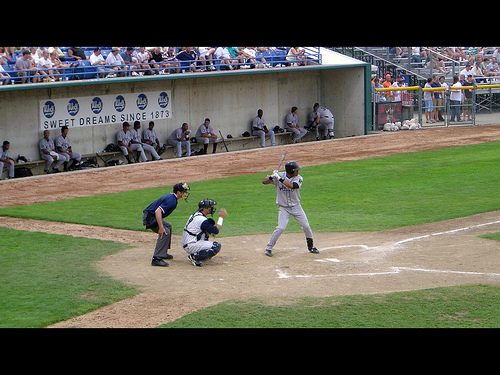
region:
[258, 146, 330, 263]
batter standing in the batter's box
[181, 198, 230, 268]
catcher crouched in the dirt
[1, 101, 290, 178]
baseball players sitting on the bench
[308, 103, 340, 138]
baseball player standing up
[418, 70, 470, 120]
spectators standing behind the chain link fence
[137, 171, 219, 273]
umpire hunched over behind the catcher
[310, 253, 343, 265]
homeplate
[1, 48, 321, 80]
spectators sitting in the stands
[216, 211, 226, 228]
thick white band on the arm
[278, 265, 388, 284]
white lines painted in the dirt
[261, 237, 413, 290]
Batter's box at a baseball field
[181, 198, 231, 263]
Catcher preparing to catch a pitch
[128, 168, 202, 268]
Umpire preparing to call a pitch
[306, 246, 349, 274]
Home plate in a baseball diamond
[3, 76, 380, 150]
Dugout area of baseball field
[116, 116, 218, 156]
Baseball players waiting to bat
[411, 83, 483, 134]
Steel gates for access to baseball field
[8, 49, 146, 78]
Spectators at a baseball game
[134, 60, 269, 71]
Safety railing for spectator area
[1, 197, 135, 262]
Path in grass leading to batter's box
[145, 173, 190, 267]
umpire behind catcher at home plate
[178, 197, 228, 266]
catcher awaiting ball to be thrown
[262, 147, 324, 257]
batter waiting for pitch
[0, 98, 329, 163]
players waiting in the dugout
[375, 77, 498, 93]
yellow guards on top of fence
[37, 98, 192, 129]
blue and white banner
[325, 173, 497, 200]
green grass on field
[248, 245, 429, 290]
home plate with scuff marks from sliders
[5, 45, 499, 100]
fans in the background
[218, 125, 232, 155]
bat leaning on bench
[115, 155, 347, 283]
baseball players on a field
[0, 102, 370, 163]
baseball players sitting on a long bench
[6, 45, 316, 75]
spectators watching baseball in the bleachers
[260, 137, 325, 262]
man holding a baseball bat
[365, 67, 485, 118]
people watching baseball behind a fence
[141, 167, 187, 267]
umpire wearing a blue shirt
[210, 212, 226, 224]
catcher wearing a white wristband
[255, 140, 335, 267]
baseball player ready to hit a ball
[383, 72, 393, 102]
man wearing an orange shirt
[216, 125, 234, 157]
a baseball bat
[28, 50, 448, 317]
man playing baseball on field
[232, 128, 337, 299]
man holding baseball bat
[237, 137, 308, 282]
man about to swing baseball bat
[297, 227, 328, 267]
front leg shin guard on man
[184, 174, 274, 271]
catcher behind man with bat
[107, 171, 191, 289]
umpire on baseball field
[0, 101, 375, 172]
team in the dugout at baseball game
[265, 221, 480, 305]
chalk outline of baseball field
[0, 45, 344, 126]
crowd sitting in the stands at game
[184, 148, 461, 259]
grass on baseball field